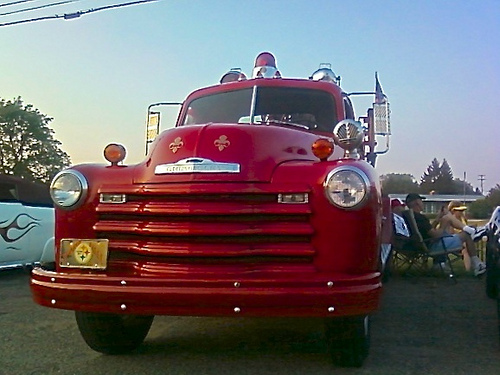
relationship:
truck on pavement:
[27, 49, 396, 368] [1, 271, 496, 372]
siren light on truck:
[254, 52, 280, 79] [27, 49, 396, 368]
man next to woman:
[400, 191, 482, 280] [439, 196, 499, 275]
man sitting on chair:
[400, 191, 482, 280] [393, 207, 457, 283]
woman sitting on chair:
[439, 196, 499, 275] [437, 227, 489, 287]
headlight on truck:
[47, 167, 91, 213] [27, 49, 396, 368]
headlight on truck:
[324, 163, 372, 216] [27, 49, 396, 368]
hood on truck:
[51, 120, 349, 187] [27, 49, 396, 368]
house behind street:
[382, 194, 490, 221] [1, 271, 496, 372]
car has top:
[2, 173, 75, 269] [1, 176, 62, 211]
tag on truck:
[55, 233, 112, 271] [27, 49, 396, 368]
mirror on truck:
[368, 91, 392, 136] [27, 49, 396, 368]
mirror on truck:
[147, 107, 162, 143] [27, 49, 396, 368]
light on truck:
[254, 52, 280, 79] [27, 49, 396, 368]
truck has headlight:
[27, 49, 396, 368] [47, 167, 91, 213]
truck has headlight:
[27, 49, 396, 368] [324, 163, 372, 216]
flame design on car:
[1, 212, 45, 243] [2, 173, 75, 269]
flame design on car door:
[1, 212, 45, 243] [1, 203, 47, 267]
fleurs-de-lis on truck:
[167, 138, 187, 151] [27, 49, 396, 368]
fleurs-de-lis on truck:
[212, 135, 232, 154] [27, 49, 396, 368]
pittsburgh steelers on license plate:
[73, 242, 94, 264] [55, 233, 112, 271]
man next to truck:
[400, 191, 482, 280] [27, 49, 396, 368]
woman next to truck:
[439, 196, 499, 275] [27, 49, 396, 368]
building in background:
[382, 194, 490, 221] [2, 3, 498, 266]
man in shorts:
[400, 191, 482, 280] [421, 235, 471, 261]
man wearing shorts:
[400, 191, 482, 280] [421, 235, 471, 261]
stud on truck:
[329, 307, 335, 314] [27, 49, 396, 368]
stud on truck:
[233, 305, 242, 318] [27, 49, 396, 368]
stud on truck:
[121, 305, 125, 311] [27, 49, 396, 368]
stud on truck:
[50, 300, 57, 308] [27, 49, 396, 368]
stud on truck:
[233, 281, 241, 288] [27, 49, 396, 368]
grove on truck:
[89, 253, 316, 268] [27, 49, 396, 368]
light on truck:
[218, 74, 249, 84] [27, 49, 396, 368]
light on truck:
[308, 65, 342, 86] [27, 49, 396, 368]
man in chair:
[400, 191, 482, 280] [393, 207, 457, 283]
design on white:
[1, 212, 45, 243] [2, 173, 75, 269]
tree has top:
[2, 97, 73, 206] [2, 97, 73, 162]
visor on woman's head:
[448, 203, 471, 212] [445, 196, 472, 224]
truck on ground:
[27, 49, 396, 368] [1, 271, 496, 372]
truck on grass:
[27, 49, 396, 368] [1, 271, 496, 372]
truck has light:
[27, 49, 396, 368] [324, 163, 372, 216]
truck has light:
[27, 49, 396, 368] [47, 167, 91, 213]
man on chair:
[400, 191, 482, 280] [393, 207, 457, 283]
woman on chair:
[439, 196, 499, 275] [437, 227, 489, 287]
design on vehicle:
[1, 212, 45, 243] [2, 173, 75, 269]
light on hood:
[102, 144, 128, 165] [51, 120, 349, 187]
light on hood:
[309, 140, 338, 164] [51, 120, 349, 187]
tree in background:
[2, 97, 73, 206] [2, 3, 498, 266]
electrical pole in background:
[474, 174, 489, 199] [2, 3, 498, 266]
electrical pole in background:
[460, 167, 469, 196] [2, 3, 498, 266]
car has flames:
[2, 173, 75, 269] [1, 212, 45, 243]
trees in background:
[414, 160, 458, 193] [2, 3, 498, 266]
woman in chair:
[439, 196, 499, 275] [437, 227, 489, 287]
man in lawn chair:
[400, 191, 482, 280] [393, 207, 457, 283]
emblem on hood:
[167, 138, 187, 151] [51, 120, 349, 187]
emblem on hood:
[212, 135, 232, 154] [51, 120, 349, 187]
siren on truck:
[254, 52, 280, 79] [27, 49, 396, 368]